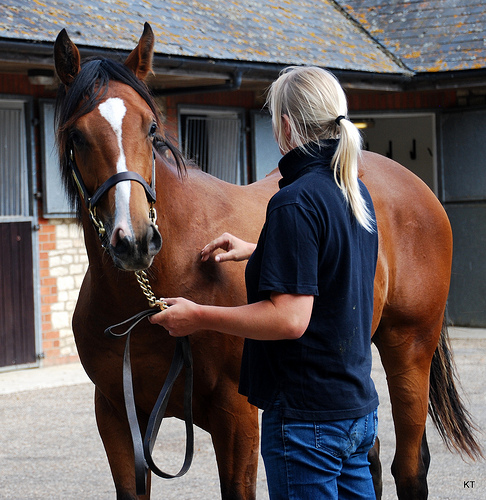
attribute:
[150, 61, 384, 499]
lady — rider, blonde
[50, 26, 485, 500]
horse — brown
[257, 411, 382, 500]
jeans — blue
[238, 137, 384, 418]
shirt — dark blue, blue, black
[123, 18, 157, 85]
ear — large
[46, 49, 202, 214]
mane — black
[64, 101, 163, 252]
bridle — leather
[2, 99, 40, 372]
stable door — wooden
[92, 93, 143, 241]
stripe — white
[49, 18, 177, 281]
horse's face — brown, white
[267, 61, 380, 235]
hair — light blond, blonde, long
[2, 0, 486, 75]
roof — grey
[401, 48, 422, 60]
spot — brown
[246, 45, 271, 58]
spot — brown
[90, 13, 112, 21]
spot — brown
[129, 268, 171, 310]
chain — gold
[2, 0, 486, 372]
building — brick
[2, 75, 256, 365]
bricks — red, brown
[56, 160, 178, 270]
nose — white